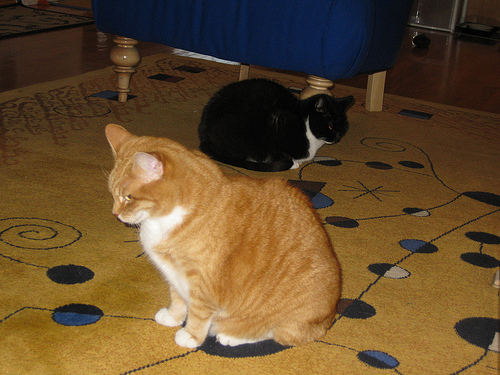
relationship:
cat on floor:
[208, 77, 351, 179] [12, 36, 493, 367]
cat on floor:
[197, 77, 358, 172] [4, 6, 494, 373]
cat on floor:
[197, 77, 358, 172] [12, 36, 493, 367]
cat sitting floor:
[197, 77, 358, 172] [5, 170, 94, 340]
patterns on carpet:
[367, 234, 437, 282] [369, 206, 483, 366]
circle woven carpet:
[51, 301, 102, 329] [11, 210, 117, 351]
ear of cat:
[106, 121, 128, 156] [96, 121, 346, 347]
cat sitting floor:
[96, 121, 346, 347] [17, 157, 106, 338]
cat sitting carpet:
[96, 121, 346, 347] [19, 222, 119, 345]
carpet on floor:
[19, 222, 119, 345] [17, 157, 106, 338]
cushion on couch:
[91, 3, 413, 99] [94, 3, 414, 41]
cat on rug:
[96, 121, 346, 347] [27, 233, 130, 338]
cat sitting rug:
[96, 121, 346, 347] [27, 233, 130, 338]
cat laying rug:
[197, 77, 358, 172] [333, 152, 385, 202]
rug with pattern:
[361, 137, 488, 358] [363, 220, 482, 287]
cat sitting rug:
[197, 77, 358, 172] [356, 221, 412, 319]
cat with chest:
[101, 122, 343, 348] [124, 204, 238, 314]